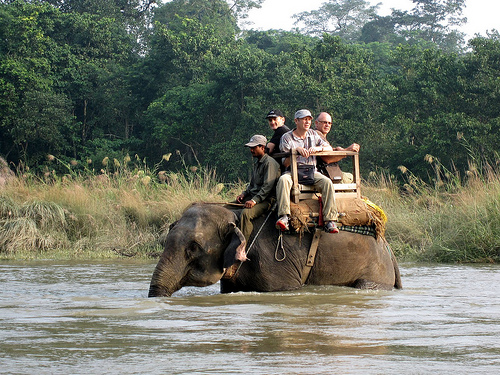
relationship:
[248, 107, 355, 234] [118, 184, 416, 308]
four men riding elephant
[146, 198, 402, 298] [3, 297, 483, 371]
elephant walking through water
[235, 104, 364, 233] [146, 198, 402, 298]
people riding elephant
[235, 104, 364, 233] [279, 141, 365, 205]
people are inside structure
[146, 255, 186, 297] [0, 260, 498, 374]
trunk in water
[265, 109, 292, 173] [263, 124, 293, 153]
man wearing shirt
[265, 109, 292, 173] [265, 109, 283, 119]
man wearing black hat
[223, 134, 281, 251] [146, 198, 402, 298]
man riding elephant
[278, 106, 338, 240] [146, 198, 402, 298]
man riding elephant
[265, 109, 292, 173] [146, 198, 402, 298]
man riding elephant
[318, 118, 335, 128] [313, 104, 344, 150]
glasses on man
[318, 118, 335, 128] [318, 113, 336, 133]
glasses on face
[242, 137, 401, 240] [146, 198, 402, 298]
saddle on elephant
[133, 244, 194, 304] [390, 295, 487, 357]
trunk in water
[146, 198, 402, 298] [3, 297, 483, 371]
elephant in water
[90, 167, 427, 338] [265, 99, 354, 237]
elephant giving a ride to passengers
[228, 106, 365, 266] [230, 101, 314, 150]
men wearing hats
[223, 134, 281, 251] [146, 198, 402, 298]
man steering elephant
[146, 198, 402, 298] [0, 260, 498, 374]
elephant in water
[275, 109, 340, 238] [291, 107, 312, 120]
man wearing gray hat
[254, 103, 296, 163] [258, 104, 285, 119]
man wearing black hat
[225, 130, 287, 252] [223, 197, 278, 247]
man wearing pants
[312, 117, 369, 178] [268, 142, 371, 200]
man holding on to crate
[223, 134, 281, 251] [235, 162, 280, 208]
man wearing shirt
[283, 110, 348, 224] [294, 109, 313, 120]
man wearing gray hat